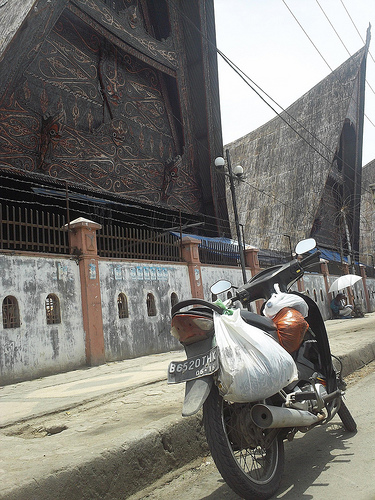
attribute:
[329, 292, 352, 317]
person — sitting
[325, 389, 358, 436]
front wheel — turned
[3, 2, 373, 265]
steep roofs — tall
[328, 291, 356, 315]
person — sitting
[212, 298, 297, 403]
bag — plastic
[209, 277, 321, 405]
bags — grocery, hanging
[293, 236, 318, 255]
mirror — side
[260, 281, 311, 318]
plastic bag — white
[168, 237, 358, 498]
motorcycle — small, parked, black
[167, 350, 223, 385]
plate — white, black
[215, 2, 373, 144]
wires — overhead, electric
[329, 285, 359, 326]
person — holding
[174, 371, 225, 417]
guard — mud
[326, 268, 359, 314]
umbrella — open, white